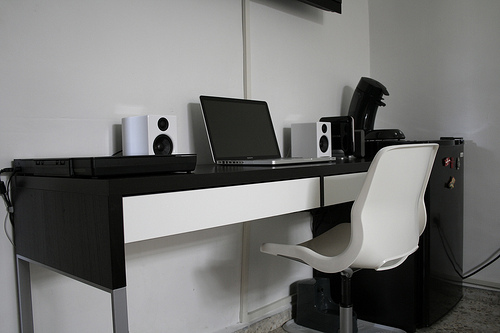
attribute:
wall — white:
[43, 5, 474, 150]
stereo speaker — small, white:
[117, 110, 187, 166]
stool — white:
[305, 117, 449, 274]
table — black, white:
[8, 134, 498, 299]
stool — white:
[257, 141, 439, 274]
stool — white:
[328, 159, 413, 279]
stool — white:
[274, 143, 460, 289]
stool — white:
[258, 140, 439, 331]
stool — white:
[282, 126, 447, 301]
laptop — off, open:
[198, 94, 335, 167]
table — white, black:
[11, 150, 372, 292]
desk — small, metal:
[6, 149, 374, 327]